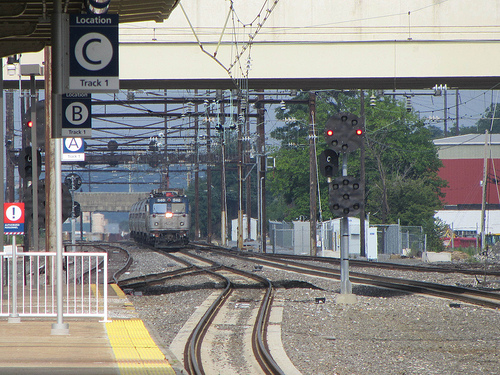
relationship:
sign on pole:
[67, 9, 120, 92] [50, 2, 72, 335]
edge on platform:
[91, 280, 169, 370] [4, 280, 174, 370]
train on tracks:
[128, 190, 187, 248] [27, 237, 483, 373]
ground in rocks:
[3, 235, 484, 366] [10, 240, 484, 368]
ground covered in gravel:
[3, 235, 500, 374] [132, 250, 497, 373]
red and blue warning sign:
[4, 173, 32, 293] [4, 193, 22, 232]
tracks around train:
[205, 264, 284, 372] [140, 186, 196, 243]